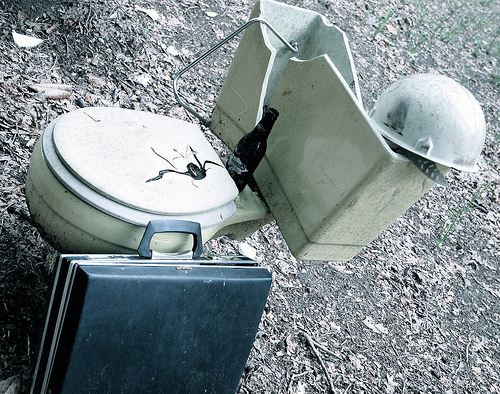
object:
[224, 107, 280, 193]
bottle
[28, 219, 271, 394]
briefcase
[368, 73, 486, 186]
helmet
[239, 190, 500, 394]
leaves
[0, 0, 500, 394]
ground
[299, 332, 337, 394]
twig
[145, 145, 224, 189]
stain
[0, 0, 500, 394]
toilet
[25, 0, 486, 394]
pile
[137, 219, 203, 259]
handle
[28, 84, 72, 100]
leaf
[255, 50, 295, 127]
crack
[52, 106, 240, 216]
lid